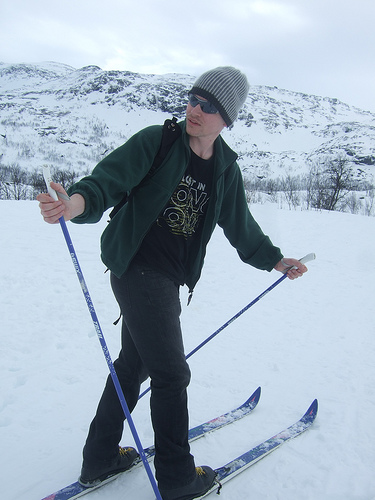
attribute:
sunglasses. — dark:
[179, 92, 218, 115]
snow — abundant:
[284, 298, 347, 370]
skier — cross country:
[37, 65, 300, 498]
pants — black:
[72, 252, 198, 493]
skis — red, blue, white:
[117, 377, 319, 461]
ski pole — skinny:
[138, 252, 315, 400]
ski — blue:
[217, 380, 288, 444]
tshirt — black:
[118, 139, 221, 289]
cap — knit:
[189, 53, 253, 128]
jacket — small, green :
[66, 119, 284, 304]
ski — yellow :
[217, 384, 318, 486]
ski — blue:
[42, 385, 261, 498]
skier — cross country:
[44, 64, 330, 495]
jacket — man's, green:
[80, 131, 283, 284]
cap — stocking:
[187, 61, 252, 130]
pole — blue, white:
[57, 177, 178, 428]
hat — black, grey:
[190, 64, 248, 117]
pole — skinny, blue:
[40, 161, 163, 471]